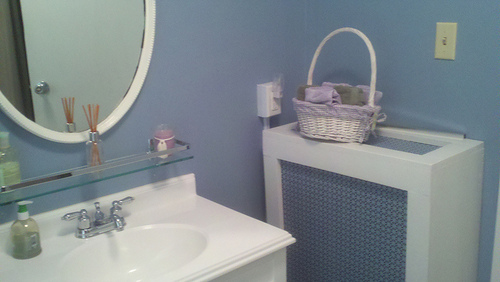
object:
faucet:
[60, 192, 133, 237]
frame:
[0, 2, 159, 146]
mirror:
[2, 0, 144, 131]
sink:
[56, 223, 207, 280]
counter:
[2, 171, 296, 280]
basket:
[293, 27, 385, 147]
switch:
[433, 20, 459, 63]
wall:
[307, 2, 497, 280]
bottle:
[82, 127, 105, 168]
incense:
[81, 97, 103, 164]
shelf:
[0, 151, 198, 212]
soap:
[7, 195, 44, 259]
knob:
[32, 78, 51, 96]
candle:
[151, 124, 177, 161]